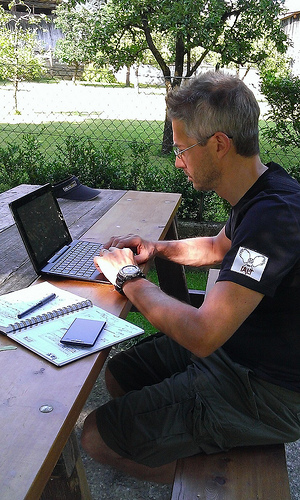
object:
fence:
[0, 63, 300, 223]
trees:
[0, 0, 300, 155]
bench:
[0, 182, 182, 499]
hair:
[165, 69, 260, 157]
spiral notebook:
[8, 281, 93, 354]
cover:
[14, 304, 146, 368]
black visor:
[51, 175, 101, 201]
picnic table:
[0, 181, 292, 500]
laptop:
[8, 181, 114, 285]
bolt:
[40, 404, 54, 414]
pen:
[17, 293, 56, 319]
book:
[0, 279, 144, 368]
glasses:
[173, 130, 232, 159]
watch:
[115, 264, 146, 296]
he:
[80, 70, 300, 487]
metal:
[115, 277, 125, 287]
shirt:
[214, 161, 300, 391]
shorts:
[95, 333, 300, 467]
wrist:
[112, 264, 145, 290]